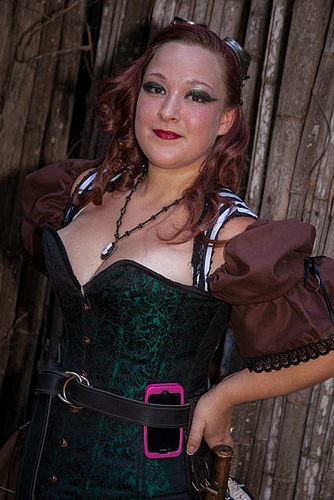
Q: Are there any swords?
A: Yes, there is a sword.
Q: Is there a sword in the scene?
A: Yes, there is a sword.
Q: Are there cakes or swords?
A: Yes, there is a sword.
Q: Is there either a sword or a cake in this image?
A: Yes, there is a sword.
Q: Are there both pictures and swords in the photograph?
A: No, there is a sword but no pictures.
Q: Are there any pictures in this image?
A: No, there are no pictures.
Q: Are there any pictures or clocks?
A: No, there are no pictures or clocks.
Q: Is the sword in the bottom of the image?
A: Yes, the sword is in the bottom of the image.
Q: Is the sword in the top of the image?
A: No, the sword is in the bottom of the image.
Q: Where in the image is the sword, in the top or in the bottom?
A: The sword is in the bottom of the image.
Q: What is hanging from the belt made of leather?
A: The sword is hanging from the belt.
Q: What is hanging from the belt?
A: The sword is hanging from the belt.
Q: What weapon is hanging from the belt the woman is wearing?
A: The weapon is a sword.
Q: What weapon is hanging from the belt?
A: The weapon is a sword.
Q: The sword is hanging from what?
A: The sword is hanging from the belt.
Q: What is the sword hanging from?
A: The sword is hanging from the belt.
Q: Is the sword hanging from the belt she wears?
A: Yes, the sword is hanging from the belt.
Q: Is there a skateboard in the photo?
A: No, there are no skateboards.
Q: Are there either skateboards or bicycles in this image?
A: No, there are no skateboards or bicycles.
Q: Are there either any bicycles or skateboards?
A: No, there are no skateboards or bicycles.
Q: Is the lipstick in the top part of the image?
A: Yes, the lipstick is in the top of the image.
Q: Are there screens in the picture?
A: No, there are no screens.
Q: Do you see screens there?
A: No, there are no screens.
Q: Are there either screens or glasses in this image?
A: No, there are no screens or glasses.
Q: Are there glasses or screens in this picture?
A: No, there are no screens or glasses.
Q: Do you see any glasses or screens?
A: No, there are no screens or glasses.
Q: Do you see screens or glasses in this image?
A: No, there are no screens or glasses.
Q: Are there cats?
A: No, there are no cats.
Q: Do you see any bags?
A: No, there are no bags.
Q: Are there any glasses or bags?
A: No, there are no bags or glasses.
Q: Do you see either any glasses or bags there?
A: No, there are no bags or glasses.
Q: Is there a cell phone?
A: Yes, there is a cell phone.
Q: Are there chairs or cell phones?
A: Yes, there is a cell phone.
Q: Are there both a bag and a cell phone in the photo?
A: No, there is a cell phone but no bags.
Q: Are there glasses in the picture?
A: No, there are no glasses.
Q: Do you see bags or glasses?
A: No, there are no glasses or bags.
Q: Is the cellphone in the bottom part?
A: Yes, the cellphone is in the bottom of the image.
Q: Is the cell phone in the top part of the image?
A: No, the cell phone is in the bottom of the image.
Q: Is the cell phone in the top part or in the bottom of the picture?
A: The cell phone is in the bottom of the image.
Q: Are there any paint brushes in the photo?
A: No, there are no paint brushes.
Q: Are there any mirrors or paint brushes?
A: No, there are no paint brushes or mirrors.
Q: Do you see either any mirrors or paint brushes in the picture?
A: No, there are no paint brushes or mirrors.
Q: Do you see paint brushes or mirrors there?
A: No, there are no paint brushes or mirrors.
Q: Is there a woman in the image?
A: Yes, there is a woman.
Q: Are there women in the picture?
A: Yes, there is a woman.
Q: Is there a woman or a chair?
A: Yes, there is a woman.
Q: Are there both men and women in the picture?
A: No, there is a woman but no men.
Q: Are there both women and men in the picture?
A: No, there is a woman but no men.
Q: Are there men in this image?
A: No, there are no men.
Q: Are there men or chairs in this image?
A: No, there are no men or chairs.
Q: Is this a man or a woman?
A: This is a woman.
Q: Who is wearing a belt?
A: The woman is wearing a belt.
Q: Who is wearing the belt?
A: The woman is wearing a belt.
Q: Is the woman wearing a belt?
A: Yes, the woman is wearing a belt.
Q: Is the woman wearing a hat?
A: No, the woman is wearing a belt.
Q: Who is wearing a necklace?
A: The woman is wearing a necklace.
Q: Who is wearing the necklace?
A: The woman is wearing a necklace.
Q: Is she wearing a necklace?
A: Yes, the woman is wearing a necklace.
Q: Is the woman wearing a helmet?
A: No, the woman is wearing a necklace.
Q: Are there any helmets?
A: No, there are no helmets.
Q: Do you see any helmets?
A: No, there are no helmets.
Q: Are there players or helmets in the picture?
A: No, there are no helmets or players.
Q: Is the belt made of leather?
A: Yes, the belt is made of leather.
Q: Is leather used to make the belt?
A: Yes, the belt is made of leather.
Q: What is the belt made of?
A: The belt is made of leather.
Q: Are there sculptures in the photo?
A: No, there are no sculptures.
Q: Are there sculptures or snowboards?
A: No, there are no sculptures or snowboards.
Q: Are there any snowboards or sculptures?
A: No, there are no sculptures or snowboards.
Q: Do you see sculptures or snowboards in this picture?
A: No, there are no sculptures or snowboards.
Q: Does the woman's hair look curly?
A: Yes, the hair is curly.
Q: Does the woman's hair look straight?
A: No, the hair is curly.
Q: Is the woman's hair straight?
A: No, the hair is curly.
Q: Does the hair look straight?
A: No, the hair is curly.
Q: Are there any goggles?
A: Yes, there are goggles.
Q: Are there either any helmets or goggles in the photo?
A: Yes, there are goggles.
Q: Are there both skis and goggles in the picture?
A: No, there are goggles but no skis.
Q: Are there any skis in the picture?
A: No, there are no skis.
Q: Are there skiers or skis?
A: No, there are no skis or skiers.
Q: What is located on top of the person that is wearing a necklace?
A: The goggles are on top of the woman.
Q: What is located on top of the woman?
A: The goggles are on top of the woman.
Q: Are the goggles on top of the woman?
A: Yes, the goggles are on top of the woman.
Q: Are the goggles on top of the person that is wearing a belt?
A: Yes, the goggles are on top of the woman.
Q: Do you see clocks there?
A: No, there are no clocks.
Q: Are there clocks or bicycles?
A: No, there are no clocks or bicycles.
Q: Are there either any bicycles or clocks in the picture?
A: No, there are no clocks or bicycles.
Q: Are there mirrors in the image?
A: No, there are no mirrors.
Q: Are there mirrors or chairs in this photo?
A: No, there are no mirrors or chairs.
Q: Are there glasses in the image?
A: No, there are no glasses.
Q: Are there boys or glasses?
A: No, there are no glasses or boys.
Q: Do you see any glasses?
A: No, there are no glasses.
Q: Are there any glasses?
A: No, there are no glasses.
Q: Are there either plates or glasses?
A: No, there are no glasses or plates.